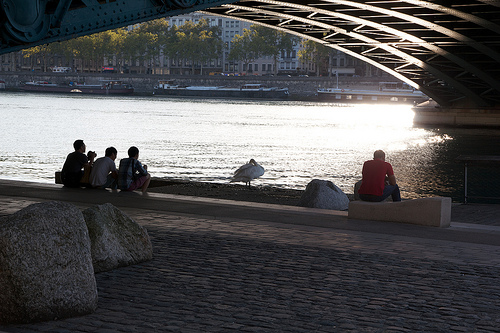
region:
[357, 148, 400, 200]
Man in red shirt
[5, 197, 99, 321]
Large gray rock on cobblestone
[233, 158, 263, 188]
White bird resting near people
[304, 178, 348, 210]
Gray rock near man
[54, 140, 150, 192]
Three people sitting near water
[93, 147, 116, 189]
Man in white shirt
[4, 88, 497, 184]
Wide river in front of people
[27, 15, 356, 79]
Trees on far side of river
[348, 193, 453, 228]
Tan block with man on it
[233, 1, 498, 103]
Metal grid under bridge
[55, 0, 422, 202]
four people under a bridge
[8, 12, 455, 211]
four people sitting under a bridge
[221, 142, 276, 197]
a large goose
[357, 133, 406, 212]
a man wearing a red shirt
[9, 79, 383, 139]
a body of water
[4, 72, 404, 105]
three large boats docked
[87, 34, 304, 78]
a row of green trees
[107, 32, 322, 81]
several buildings in a row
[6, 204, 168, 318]
two large rocks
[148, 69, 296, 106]
a large boat docked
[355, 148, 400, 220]
man sitting on a cement block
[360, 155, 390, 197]
red tee shirt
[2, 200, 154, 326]
rocks under the bridge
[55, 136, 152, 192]
three men sitting by the water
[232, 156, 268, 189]
a fat bird by the water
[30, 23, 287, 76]
trees by the building in the back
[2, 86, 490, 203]
a river beneath the bridge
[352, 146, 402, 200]
a man facing the water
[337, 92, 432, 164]
sunlight reflecting off of the water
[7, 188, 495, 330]
stone pathway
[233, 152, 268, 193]
bird on the edge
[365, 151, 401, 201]
man sitting on a box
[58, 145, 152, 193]
three people sitting together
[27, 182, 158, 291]
large rocks on the sidewalk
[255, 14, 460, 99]
overpass is curved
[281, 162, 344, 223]
rock on the edge of water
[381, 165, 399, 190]
man has a red shirt on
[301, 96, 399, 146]
sun reflection on the water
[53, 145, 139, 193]
three guys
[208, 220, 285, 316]
walkway is made of bricks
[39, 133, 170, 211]
three boys sit on border of sidewalk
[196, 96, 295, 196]
a bird in front a river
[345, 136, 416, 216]
a man sit in front a river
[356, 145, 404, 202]
man wears a red shirt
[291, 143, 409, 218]
man sits next a big rock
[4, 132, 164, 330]
two big rocks behind three boys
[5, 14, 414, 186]
a river in front buildings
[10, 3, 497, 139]
a bridge over a river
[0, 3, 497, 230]
people are under a bridge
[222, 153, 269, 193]
a white bird touching his back